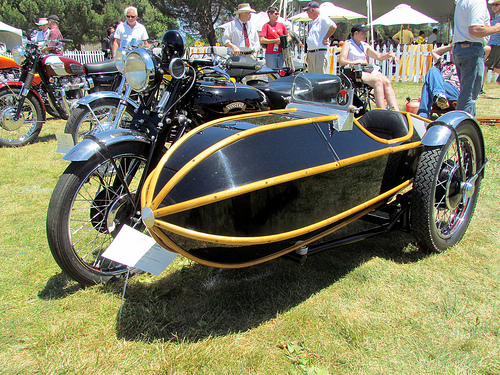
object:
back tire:
[408, 119, 483, 252]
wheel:
[46, 140, 167, 287]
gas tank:
[200, 84, 263, 115]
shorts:
[355, 68, 381, 77]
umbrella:
[364, 4, 439, 26]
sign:
[101, 223, 178, 277]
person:
[338, 24, 399, 113]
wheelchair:
[334, 51, 396, 111]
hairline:
[128, 7, 137, 10]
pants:
[306, 49, 327, 75]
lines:
[149, 114, 340, 208]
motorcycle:
[43, 78, 441, 286]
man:
[111, 6, 149, 59]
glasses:
[126, 15, 135, 18]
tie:
[243, 23, 251, 48]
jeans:
[416, 65, 462, 119]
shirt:
[259, 22, 288, 55]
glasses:
[272, 12, 279, 15]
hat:
[350, 24, 370, 33]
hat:
[233, 2, 256, 14]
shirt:
[221, 18, 262, 53]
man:
[222, 3, 262, 66]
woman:
[338, 24, 400, 112]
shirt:
[345, 38, 370, 66]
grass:
[315, 290, 479, 363]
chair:
[335, 52, 381, 110]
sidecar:
[139, 98, 435, 270]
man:
[305, 0, 337, 75]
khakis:
[307, 48, 329, 74]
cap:
[302, 1, 319, 12]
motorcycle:
[0, 40, 121, 148]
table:
[390, 44, 433, 81]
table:
[304, 48, 335, 74]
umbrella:
[288, 0, 367, 21]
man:
[451, 0, 500, 117]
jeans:
[452, 42, 484, 118]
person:
[260, 6, 291, 69]